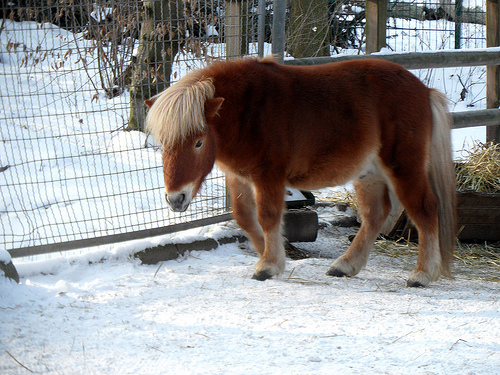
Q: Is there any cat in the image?
A: No, there are no cats.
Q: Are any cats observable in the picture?
A: No, there are no cats.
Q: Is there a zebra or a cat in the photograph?
A: No, there are no cats or zebras.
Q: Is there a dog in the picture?
A: No, there are no dogs.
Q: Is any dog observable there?
A: No, there are no dogs.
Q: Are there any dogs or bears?
A: No, there are no dogs or bears.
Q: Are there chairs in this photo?
A: No, there are no chairs.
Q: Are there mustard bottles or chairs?
A: No, there are no chairs or mustard bottles.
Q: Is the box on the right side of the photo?
A: Yes, the box is on the right of the image.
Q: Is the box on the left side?
A: No, the box is on the right of the image.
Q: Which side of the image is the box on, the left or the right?
A: The box is on the right of the image.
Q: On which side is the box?
A: The box is on the right of the image.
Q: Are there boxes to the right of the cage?
A: Yes, there is a box to the right of the cage.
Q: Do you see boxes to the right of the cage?
A: Yes, there is a box to the right of the cage.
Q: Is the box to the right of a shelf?
A: No, the box is to the right of the cage.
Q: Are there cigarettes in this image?
A: No, there are no cigarettes.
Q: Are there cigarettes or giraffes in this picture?
A: No, there are no cigarettes or giraffes.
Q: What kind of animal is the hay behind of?
A: The hay is behind the horse.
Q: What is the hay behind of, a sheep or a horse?
A: The hay is behind a horse.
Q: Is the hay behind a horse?
A: Yes, the hay is behind a horse.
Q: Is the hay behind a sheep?
A: No, the hay is behind a horse.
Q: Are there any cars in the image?
A: No, there are no cars.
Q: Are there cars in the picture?
A: No, there are no cars.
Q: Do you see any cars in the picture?
A: No, there are no cars.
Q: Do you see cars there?
A: No, there are no cars.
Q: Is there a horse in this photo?
A: Yes, there is a horse.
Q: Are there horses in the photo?
A: Yes, there is a horse.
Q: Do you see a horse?
A: Yes, there is a horse.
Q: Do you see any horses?
A: Yes, there is a horse.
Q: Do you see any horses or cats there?
A: Yes, there is a horse.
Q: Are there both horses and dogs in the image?
A: No, there is a horse but no dogs.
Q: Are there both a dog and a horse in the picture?
A: No, there is a horse but no dogs.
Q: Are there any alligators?
A: No, there are no alligators.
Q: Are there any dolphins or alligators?
A: No, there are no alligators or dolphins.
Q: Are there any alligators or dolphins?
A: No, there are no alligators or dolphins.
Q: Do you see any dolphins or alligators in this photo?
A: No, there are no alligators or dolphins.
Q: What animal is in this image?
A: The animal is a horse.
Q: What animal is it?
A: The animal is a horse.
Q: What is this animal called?
A: This is a horse.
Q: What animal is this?
A: This is a horse.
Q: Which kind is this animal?
A: This is a horse.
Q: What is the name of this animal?
A: This is a horse.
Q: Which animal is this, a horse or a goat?
A: This is a horse.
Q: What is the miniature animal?
A: The animal is a horse.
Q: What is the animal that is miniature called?
A: The animal is a horse.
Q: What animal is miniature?
A: The animal is a horse.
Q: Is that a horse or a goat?
A: That is a horse.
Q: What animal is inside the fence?
A: The horse is inside the fence.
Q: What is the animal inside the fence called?
A: The animal is a horse.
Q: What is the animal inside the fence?
A: The animal is a horse.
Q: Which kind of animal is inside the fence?
A: The animal is a horse.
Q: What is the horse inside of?
A: The horse is inside the fence.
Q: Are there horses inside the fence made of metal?
A: Yes, there is a horse inside the fence.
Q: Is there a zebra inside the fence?
A: No, there is a horse inside the fence.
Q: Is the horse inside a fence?
A: Yes, the horse is inside a fence.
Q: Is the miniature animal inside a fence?
A: Yes, the horse is inside a fence.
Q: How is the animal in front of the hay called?
A: The animal is a horse.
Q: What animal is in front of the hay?
A: The animal is a horse.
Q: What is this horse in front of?
A: The horse is in front of the hay.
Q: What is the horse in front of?
A: The horse is in front of the hay.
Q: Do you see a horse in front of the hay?
A: Yes, there is a horse in front of the hay.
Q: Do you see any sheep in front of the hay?
A: No, there is a horse in front of the hay.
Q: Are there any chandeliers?
A: No, there are no chandeliers.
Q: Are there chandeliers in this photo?
A: No, there are no chandeliers.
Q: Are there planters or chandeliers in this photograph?
A: No, there are no chandeliers or planters.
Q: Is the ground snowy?
A: Yes, the ground is snowy.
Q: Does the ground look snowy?
A: Yes, the ground is snowy.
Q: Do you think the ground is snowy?
A: Yes, the ground is snowy.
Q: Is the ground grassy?
A: No, the ground is snowy.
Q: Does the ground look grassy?
A: No, the ground is snowy.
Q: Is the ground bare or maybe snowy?
A: The ground is snowy.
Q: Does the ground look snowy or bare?
A: The ground is snowy.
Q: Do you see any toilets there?
A: No, there are no toilets.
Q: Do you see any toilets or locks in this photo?
A: No, there are no toilets or locks.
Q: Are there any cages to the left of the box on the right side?
A: Yes, there is a cage to the left of the box.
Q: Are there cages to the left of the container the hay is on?
A: Yes, there is a cage to the left of the box.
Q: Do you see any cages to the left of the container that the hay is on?
A: Yes, there is a cage to the left of the box.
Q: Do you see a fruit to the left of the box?
A: No, there is a cage to the left of the box.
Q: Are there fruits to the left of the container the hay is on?
A: No, there is a cage to the left of the box.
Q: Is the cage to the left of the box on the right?
A: Yes, the cage is to the left of the box.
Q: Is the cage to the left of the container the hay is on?
A: Yes, the cage is to the left of the box.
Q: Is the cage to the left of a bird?
A: No, the cage is to the left of the box.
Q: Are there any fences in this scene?
A: Yes, there is a fence.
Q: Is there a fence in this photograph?
A: Yes, there is a fence.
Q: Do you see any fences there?
A: Yes, there is a fence.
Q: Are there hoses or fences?
A: Yes, there is a fence.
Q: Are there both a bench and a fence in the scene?
A: No, there is a fence but no benches.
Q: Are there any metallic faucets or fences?
A: Yes, there is a metal fence.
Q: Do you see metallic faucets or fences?
A: Yes, there is a metal fence.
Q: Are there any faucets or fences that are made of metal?
A: Yes, the fence is made of metal.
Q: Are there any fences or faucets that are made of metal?
A: Yes, the fence is made of metal.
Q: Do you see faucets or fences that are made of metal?
A: Yes, the fence is made of metal.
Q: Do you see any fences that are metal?
A: Yes, there is a metal fence.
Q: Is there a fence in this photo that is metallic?
A: Yes, there is a fence that is metallic.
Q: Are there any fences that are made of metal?
A: Yes, there is a fence that is made of metal.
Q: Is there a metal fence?
A: Yes, there is a fence that is made of metal.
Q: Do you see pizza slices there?
A: No, there are no pizza slices.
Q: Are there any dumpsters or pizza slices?
A: No, there are no pizza slices or dumpsters.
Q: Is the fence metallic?
A: Yes, the fence is metallic.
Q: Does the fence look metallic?
A: Yes, the fence is metallic.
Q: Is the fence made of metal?
A: Yes, the fence is made of metal.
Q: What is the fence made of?
A: The fence is made of metal.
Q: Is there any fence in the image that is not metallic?
A: No, there is a fence but it is metallic.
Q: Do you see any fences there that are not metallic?
A: No, there is a fence but it is metallic.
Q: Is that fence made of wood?
A: No, the fence is made of metal.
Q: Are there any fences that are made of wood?
A: No, there is a fence but it is made of metal.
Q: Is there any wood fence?
A: No, there is a fence but it is made of metal.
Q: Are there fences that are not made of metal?
A: No, there is a fence but it is made of metal.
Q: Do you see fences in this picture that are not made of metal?
A: No, there is a fence but it is made of metal.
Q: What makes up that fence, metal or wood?
A: The fence is made of metal.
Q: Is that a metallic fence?
A: Yes, that is a metallic fence.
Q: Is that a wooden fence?
A: No, that is a metallic fence.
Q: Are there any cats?
A: No, there are no cats.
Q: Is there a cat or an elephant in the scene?
A: No, there are no cats or elephants.